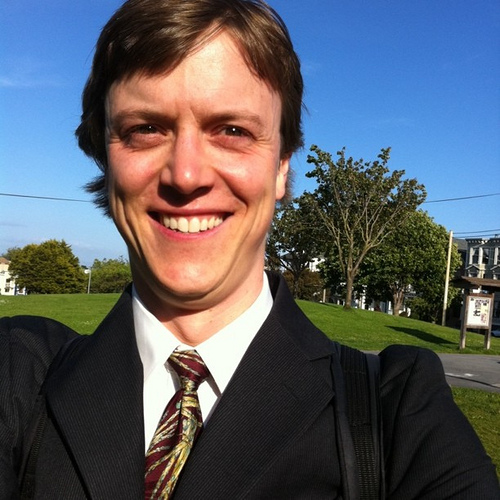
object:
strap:
[330, 344, 385, 499]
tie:
[144, 351, 212, 496]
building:
[0, 256, 28, 297]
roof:
[0, 255, 13, 264]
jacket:
[0, 269, 500, 498]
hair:
[75, 0, 311, 232]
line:
[423, 191, 498, 206]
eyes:
[121, 120, 169, 136]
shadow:
[383, 321, 461, 353]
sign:
[466, 294, 495, 327]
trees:
[261, 143, 464, 318]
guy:
[2, 2, 499, 498]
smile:
[141, 200, 238, 246]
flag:
[82, 266, 93, 275]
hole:
[80, 291, 88, 298]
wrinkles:
[252, 131, 277, 143]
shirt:
[128, 271, 276, 458]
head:
[73, 1, 311, 312]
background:
[0, 129, 499, 474]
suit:
[0, 279, 497, 497]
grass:
[0, 293, 498, 356]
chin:
[145, 243, 237, 301]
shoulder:
[306, 327, 457, 448]